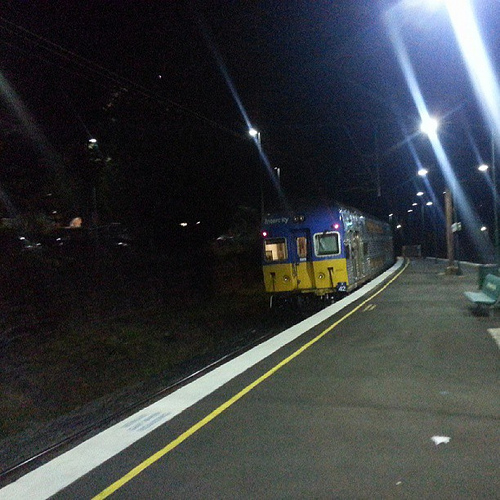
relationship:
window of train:
[314, 232, 347, 267] [257, 205, 401, 318]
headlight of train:
[316, 267, 330, 284] [254, 196, 399, 311]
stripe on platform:
[84, 256, 412, 499] [48, 250, 495, 500]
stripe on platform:
[2, 251, 406, 498] [17, 214, 495, 497]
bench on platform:
[456, 271, 498, 316] [7, 253, 499, 499]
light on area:
[234, 226, 308, 274] [259, 197, 388, 260]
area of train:
[259, 197, 388, 260] [259, 179, 427, 306]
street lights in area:
[389, 109, 496, 288] [0, 206, 493, 494]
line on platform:
[169, 356, 244, 397] [195, 323, 445, 463]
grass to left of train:
[1, 230, 266, 432] [262, 200, 402, 310]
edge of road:
[76, 390, 192, 437] [156, 330, 463, 452]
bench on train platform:
[460, 271, 499, 316] [388, 242, 468, 454]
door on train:
[291, 227, 315, 292] [255, 185, 405, 307]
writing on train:
[263, 217, 293, 223] [232, 129, 442, 313]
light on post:
[418, 167, 430, 174] [419, 199, 426, 259]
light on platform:
[418, 167, 430, 174] [7, 253, 499, 499]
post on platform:
[419, 199, 426, 259] [7, 253, 499, 499]